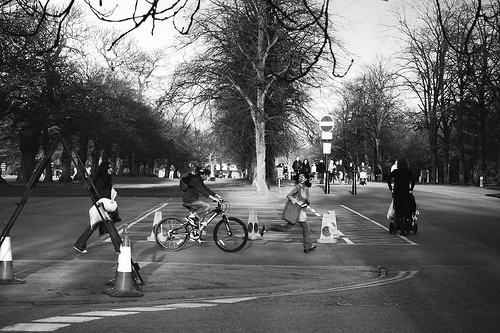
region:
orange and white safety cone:
[104, 224, 144, 299]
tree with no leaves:
[166, 5, 316, 192]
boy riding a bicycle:
[152, 156, 249, 253]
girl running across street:
[261, 171, 320, 254]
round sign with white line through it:
[317, 111, 336, 192]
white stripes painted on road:
[5, 294, 259, 331]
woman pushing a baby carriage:
[385, 155, 422, 233]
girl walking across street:
[72, 153, 131, 255]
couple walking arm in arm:
[290, 153, 310, 187]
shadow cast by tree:
[119, 178, 254, 197]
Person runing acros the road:
[263, 160, 368, 227]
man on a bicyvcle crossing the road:
[165, 161, 276, 268]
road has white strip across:
[98, 284, 220, 331]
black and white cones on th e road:
[104, 237, 146, 296]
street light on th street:
[298, 93, 364, 208]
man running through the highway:
[368, 144, 451, 262]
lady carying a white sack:
[93, 189, 126, 233]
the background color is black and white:
[123, 103, 408, 324]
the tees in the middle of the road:
[206, 29, 308, 138]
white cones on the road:
[313, 208, 341, 245]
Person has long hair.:
[95, 164, 117, 179]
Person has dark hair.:
[93, 167, 114, 189]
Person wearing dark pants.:
[70, 225, 120, 258]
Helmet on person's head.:
[191, 163, 223, 182]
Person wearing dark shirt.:
[186, 183, 208, 198]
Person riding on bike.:
[178, 185, 219, 230]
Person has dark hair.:
[292, 169, 312, 187]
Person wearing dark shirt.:
[395, 171, 415, 183]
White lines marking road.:
[356, 207, 386, 246]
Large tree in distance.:
[233, 56, 284, 217]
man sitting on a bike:
[146, 163, 268, 256]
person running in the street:
[259, 159, 318, 257]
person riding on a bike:
[377, 153, 424, 239]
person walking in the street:
[70, 156, 130, 259]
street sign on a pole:
[310, 112, 340, 197]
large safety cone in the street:
[0, 225, 28, 287]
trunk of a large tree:
[247, 119, 277, 195]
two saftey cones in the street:
[314, 205, 342, 249]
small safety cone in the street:
[240, 205, 263, 244]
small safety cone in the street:
[145, 209, 170, 244]